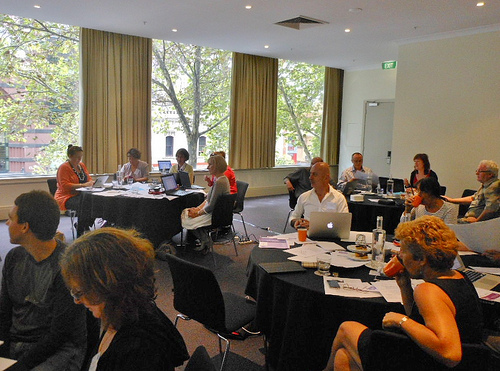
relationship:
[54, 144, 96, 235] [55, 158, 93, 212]
people wearing orange cardigan cardigan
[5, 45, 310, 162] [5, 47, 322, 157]
trees outside window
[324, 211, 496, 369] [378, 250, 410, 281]
lady holding cup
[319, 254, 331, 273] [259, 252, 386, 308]
clear cup sitting on table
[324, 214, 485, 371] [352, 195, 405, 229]
lady sitting at table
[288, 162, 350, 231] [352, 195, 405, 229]
man sitting at table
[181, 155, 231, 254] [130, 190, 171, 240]
people sitting at table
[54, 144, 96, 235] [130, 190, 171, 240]
people sitting at table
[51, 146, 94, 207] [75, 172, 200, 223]
people sitting at table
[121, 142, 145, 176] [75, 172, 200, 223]
people sitting at table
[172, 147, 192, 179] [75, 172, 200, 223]
people sitting at table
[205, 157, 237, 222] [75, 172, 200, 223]
people sitting at table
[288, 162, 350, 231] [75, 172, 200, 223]
man sitting at table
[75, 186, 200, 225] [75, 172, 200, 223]
table cloth on table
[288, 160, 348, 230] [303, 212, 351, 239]
man sitting beside laptop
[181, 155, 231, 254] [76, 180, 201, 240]
people sitting at table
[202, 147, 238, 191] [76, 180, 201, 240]
woman sitting at table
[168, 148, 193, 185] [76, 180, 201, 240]
people sitting at table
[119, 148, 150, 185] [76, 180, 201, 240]
people sitting at table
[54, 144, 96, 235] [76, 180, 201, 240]
people sitting at table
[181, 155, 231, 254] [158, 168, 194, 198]
people sitting in front of laptop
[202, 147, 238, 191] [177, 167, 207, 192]
woman sitting in front of laptop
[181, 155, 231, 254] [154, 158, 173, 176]
people sitting in front of laptop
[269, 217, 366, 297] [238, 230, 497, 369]
paper on table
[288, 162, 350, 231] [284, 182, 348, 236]
man wearing shirt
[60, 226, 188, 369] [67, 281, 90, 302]
woman wearing glasses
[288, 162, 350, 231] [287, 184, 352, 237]
man wearing shirt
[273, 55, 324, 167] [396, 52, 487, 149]
window on wall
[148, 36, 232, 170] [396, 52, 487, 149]
window on wall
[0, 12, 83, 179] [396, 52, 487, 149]
window on wall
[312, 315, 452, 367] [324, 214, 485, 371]
legs on lady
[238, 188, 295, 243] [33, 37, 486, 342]
carpeted floor in room